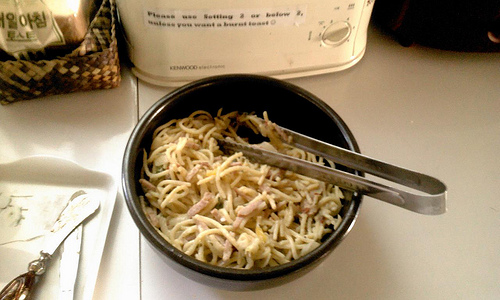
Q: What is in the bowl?
A: Noodles.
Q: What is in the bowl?
A: Tongs.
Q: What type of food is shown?
A: Pasta.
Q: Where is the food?
A: In a bowl.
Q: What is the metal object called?
A: Tongs.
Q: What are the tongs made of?
A: Metal.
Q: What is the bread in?
A: Basket.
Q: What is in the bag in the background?
A: Bread.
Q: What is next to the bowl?
A: Tray.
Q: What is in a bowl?
A: Pasta.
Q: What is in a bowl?
A: Pasta.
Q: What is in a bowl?
A: Pasta.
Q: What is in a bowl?
A: Pasta.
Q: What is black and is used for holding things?
A: A bowl.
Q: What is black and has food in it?
A: The bowl.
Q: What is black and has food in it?
A: The bowl.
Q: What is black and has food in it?
A: The bowl.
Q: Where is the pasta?
A: In a bowl.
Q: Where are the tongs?
A: In pasta.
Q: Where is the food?
A: In bowl.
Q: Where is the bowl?
A: On counter.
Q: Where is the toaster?
A: On counter.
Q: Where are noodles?
A: Bowl.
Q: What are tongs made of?
A: Metal.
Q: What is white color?
A: Noodles.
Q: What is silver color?
A: Tong.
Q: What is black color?
A: Bowl.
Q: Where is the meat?
A: In the bowl.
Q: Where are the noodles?
A: Black bowl.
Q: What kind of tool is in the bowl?
A: Tongs.